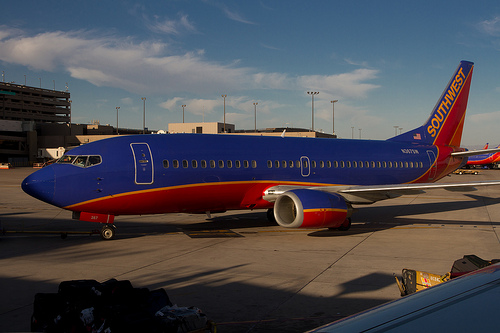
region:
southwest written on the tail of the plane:
[433, 68, 471, 152]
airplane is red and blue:
[58, 128, 413, 238]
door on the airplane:
[123, 130, 160, 198]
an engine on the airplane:
[265, 185, 352, 244]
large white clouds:
[3, 20, 400, 110]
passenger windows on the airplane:
[163, 147, 430, 179]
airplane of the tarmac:
[18, 163, 412, 259]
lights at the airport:
[108, 76, 363, 130]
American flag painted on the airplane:
[406, 131, 436, 142]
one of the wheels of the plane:
[84, 204, 177, 246]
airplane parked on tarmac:
[24, 55, 484, 252]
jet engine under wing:
[267, 182, 361, 234]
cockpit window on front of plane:
[56, 146, 103, 174]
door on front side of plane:
[123, 135, 158, 195]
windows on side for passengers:
[185, 151, 273, 174]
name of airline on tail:
[411, 58, 472, 146]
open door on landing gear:
[67, 205, 124, 246]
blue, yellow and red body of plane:
[181, 174, 243, 200]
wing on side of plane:
[351, 172, 491, 202]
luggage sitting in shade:
[24, 265, 213, 330]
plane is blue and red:
[25, 54, 495, 251]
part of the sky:
[346, 7, 386, 29]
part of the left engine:
[298, 189, 335, 235]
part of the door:
[121, 135, 158, 188]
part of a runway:
[224, 225, 278, 273]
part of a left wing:
[445, 169, 492, 189]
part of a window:
[56, 146, 98, 173]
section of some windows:
[199, 150, 334, 187]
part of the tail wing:
[412, 58, 456, 147]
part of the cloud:
[169, 62, 214, 82]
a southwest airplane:
[13, 45, 494, 242]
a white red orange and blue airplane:
[16, 31, 484, 246]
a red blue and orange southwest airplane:
[24, 60, 494, 227]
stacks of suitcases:
[21, 266, 228, 330]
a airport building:
[1, 61, 354, 186]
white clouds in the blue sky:
[8, 12, 402, 129]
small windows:
[155, 147, 447, 177]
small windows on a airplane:
[16, 42, 499, 250]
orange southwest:
[412, 30, 484, 174]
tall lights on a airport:
[93, 85, 385, 165]